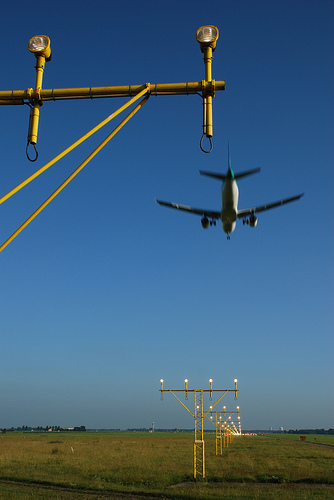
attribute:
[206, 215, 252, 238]
wheels — down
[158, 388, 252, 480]
bars — yellow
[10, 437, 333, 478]
field — grassy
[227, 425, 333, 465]
runway — airport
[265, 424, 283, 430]
structures —  in distance,  two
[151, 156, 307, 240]
airplane — green, white, flying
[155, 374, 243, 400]
lights — lit, metal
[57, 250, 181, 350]
sky — cloudless, clear, blue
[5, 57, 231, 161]
towers — yellow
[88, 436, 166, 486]
field — green, airport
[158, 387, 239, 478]
pole — yellow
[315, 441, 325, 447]
road — grey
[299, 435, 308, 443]
sign — red